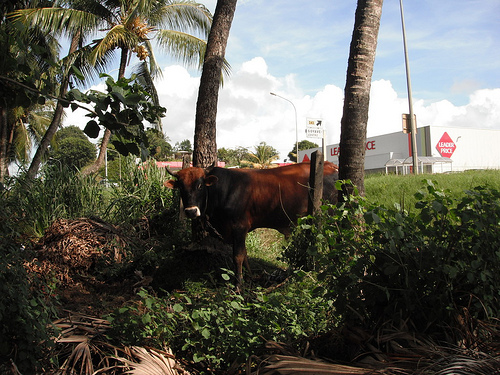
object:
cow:
[164, 161, 340, 288]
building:
[159, 161, 183, 169]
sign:
[435, 131, 458, 159]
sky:
[233, 1, 336, 55]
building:
[432, 125, 483, 169]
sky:
[377, 2, 500, 76]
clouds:
[228, 62, 269, 128]